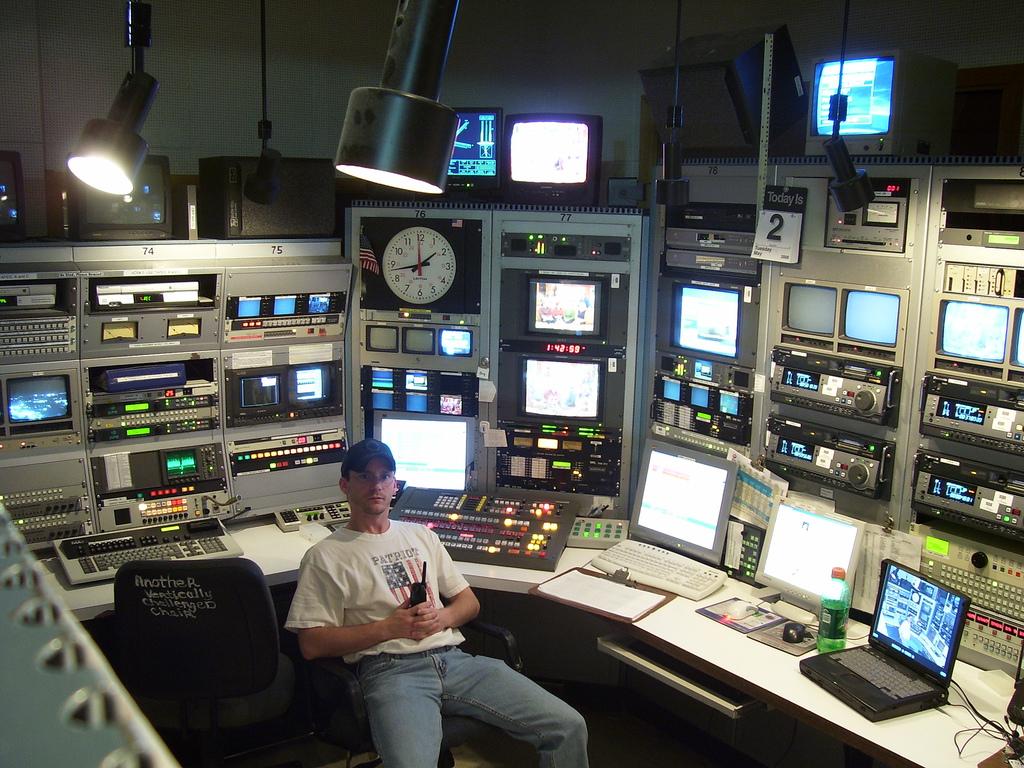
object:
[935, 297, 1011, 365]
monitor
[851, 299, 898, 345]
monitor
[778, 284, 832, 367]
monitor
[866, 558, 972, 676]
monitor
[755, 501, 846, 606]
monitor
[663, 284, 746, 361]
monitor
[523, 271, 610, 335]
monitor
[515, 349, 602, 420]
monitor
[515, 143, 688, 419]
structure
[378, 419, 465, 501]
monitor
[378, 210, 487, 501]
structure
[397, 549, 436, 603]
radio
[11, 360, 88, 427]
screen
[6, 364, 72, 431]
monitor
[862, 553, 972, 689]
screen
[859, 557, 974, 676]
monitor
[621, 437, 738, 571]
screen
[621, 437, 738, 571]
monitor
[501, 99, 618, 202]
screen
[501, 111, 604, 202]
monitor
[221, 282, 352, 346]
screen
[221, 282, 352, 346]
monitor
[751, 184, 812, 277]
number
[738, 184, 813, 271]
calendar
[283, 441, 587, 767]
man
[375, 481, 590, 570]
control board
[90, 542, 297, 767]
chair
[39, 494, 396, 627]
desk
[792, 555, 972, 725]
laptop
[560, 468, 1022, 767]
desk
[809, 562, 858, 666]
drink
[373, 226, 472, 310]
clock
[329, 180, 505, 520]
control board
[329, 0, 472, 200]
lamp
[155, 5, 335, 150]
ceiling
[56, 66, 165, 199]
light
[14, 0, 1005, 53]
ceiling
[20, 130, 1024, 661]
structure